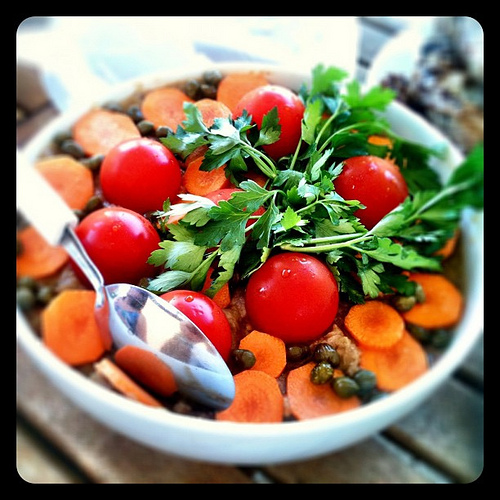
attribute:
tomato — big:
[342, 152, 404, 214]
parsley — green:
[155, 64, 479, 300]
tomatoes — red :
[252, 263, 322, 332]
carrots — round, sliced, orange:
[80, 87, 158, 152]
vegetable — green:
[99, 32, 464, 421]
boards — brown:
[20, 369, 492, 481]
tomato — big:
[241, 242, 343, 338]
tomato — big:
[70, 84, 409, 342]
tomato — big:
[98, 133, 178, 210]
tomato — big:
[68, 205, 164, 284]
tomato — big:
[156, 285, 233, 361]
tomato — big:
[240, 250, 341, 342]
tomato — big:
[205, 82, 322, 189]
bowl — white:
[18, 58, 485, 460]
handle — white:
[15, 151, 80, 252]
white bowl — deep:
[11, 58, 489, 469]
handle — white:
[14, 147, 77, 249]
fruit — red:
[186, 248, 369, 354]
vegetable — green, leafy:
[138, 73, 479, 304]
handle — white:
[8, 163, 119, 240]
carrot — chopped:
[32, 280, 120, 370]